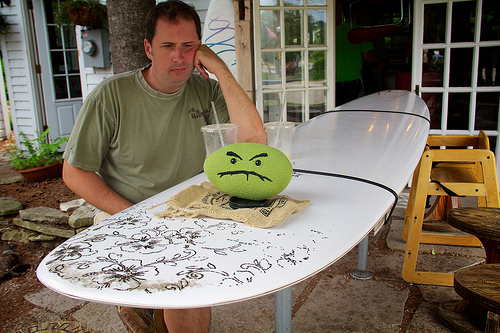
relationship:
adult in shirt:
[59, 0, 268, 332] [90, 57, 250, 204]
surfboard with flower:
[26, 79, 435, 329] [90, 257, 160, 293]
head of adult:
[140, 0, 205, 95] [41, 0, 277, 330]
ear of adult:
[144, 37, 153, 59] [59, 0, 268, 332]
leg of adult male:
[160, 307, 213, 331] [60, 0, 266, 215]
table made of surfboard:
[109, 117, 483, 278] [26, 79, 435, 329]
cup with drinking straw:
[261, 104, 300, 164] [273, 84, 291, 124]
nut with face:
[202, 141, 292, 198] [217, 152, 272, 182]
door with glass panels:
[245, 0, 355, 128] [262, 4, 319, 109]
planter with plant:
[19, 165, 52, 185] [5, 127, 69, 169]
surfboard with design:
[200, 0, 238, 81] [200, 15, 241, 55]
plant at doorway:
[5, 127, 69, 169] [28, 0, 85, 155]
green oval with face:
[198, 140, 295, 202] [220, 146, 280, 186]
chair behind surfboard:
[405, 135, 497, 302] [26, 89, 435, 303]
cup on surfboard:
[202, 119, 239, 172] [26, 89, 435, 303]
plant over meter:
[5, 127, 69, 169] [72, 28, 112, 75]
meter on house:
[75, 26, 110, 70] [2, 0, 494, 214]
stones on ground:
[14, 195, 59, 233] [2, 160, 147, 330]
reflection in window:
[258, 6, 321, 101] [255, 11, 331, 116]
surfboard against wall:
[203, 0, 238, 81] [189, 0, 208, 26]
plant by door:
[8, 127, 69, 184] [405, 0, 499, 190]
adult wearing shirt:
[59, 0, 268, 332] [60, 64, 232, 204]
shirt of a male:
[63, 64, 226, 197] [60, 2, 269, 202]